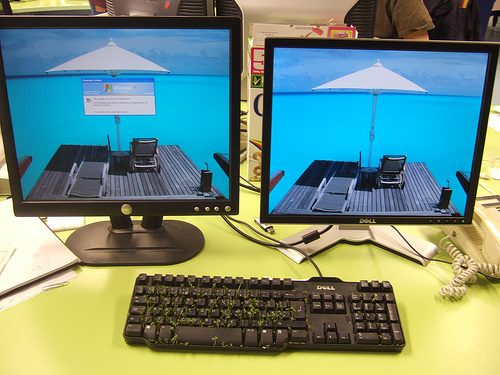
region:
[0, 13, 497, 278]
Two computer monitors turned on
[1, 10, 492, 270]
Two monitors with the same background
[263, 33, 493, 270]
Computer monitor turned on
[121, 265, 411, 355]
Black keyboard growing greenery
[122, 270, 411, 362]
Black keyboard on table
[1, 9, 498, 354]
Two monitors and a keyboard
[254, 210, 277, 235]
A USB drive on a table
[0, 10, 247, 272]
A square computer monitor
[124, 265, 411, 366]
A black keyboard growing weeds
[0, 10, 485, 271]
Two monitors with same background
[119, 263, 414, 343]
black keyboard on desk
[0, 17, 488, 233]
two computer monitors on the desk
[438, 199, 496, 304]
white phone with cord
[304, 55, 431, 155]
open umbrella on monitor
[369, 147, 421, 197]
picture of a deck chair on monitor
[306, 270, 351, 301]
The word DELL on keyboard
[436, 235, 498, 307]
white curled telephone cord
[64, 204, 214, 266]
a black computer monitor stand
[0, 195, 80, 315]
white pad of paper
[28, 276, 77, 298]
silver paperclip on light green desk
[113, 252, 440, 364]
keyboard on top of table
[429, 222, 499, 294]
cord on top of table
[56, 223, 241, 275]
stand on top of table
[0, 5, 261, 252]
monitor on top of table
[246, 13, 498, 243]
monitor on top of table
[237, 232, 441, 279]
cables on top of table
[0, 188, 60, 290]
paper on top of table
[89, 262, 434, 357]
black keyboard on top of table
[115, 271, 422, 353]
a black keyboard on top of table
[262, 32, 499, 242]
A computer monitor on right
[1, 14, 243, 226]
A computer monitor on left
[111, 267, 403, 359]
A black keyboard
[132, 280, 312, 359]
Green weeds on black keyboard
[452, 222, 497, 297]
A beige office phone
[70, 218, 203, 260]
Black monitor stand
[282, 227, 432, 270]
Silver monitor stand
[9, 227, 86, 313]
A notebook with white paper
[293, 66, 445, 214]
An umbrella and deck chairs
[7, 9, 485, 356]
a desk with 2 computer monitors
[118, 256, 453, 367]
a keyboard with plants growing in it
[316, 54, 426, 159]
a white umbrella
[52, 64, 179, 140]
a windows xp error message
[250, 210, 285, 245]
a usb flash drive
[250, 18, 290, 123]
a box of cheerios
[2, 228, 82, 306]
a paper day planner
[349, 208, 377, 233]
the logo for Dell computers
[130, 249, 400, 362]
the keyboard on the desk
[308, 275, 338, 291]
the word dell on the keyboard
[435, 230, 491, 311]
the cord on the telephone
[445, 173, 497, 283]
the telephone by the monitor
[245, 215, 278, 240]
the usb on the desk behind the monitor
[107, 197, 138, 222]
the round power button on the monitor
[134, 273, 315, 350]
the grass growing in the keyboard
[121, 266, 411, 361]
keyboard on a desk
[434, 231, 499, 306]
coiled cord of a phone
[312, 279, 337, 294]
logo on a black keyboard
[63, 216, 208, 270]
black stand of a monitor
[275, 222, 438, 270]
silver stand of a monitor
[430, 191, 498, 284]
phone on a desk